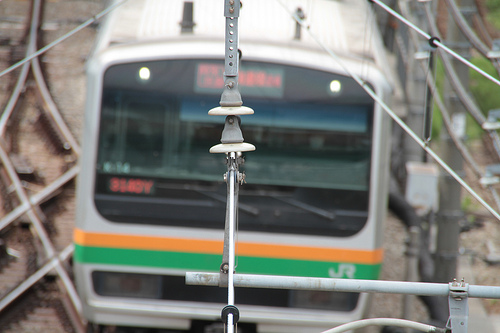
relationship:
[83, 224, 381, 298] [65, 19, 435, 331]
stripes on a train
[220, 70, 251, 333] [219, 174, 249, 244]
silver pole apparatus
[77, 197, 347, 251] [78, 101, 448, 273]
front windshield of a bus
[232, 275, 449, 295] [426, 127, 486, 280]
metal railing connected to wires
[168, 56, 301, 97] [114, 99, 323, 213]
train name and location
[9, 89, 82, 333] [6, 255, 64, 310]
railroad tracks crossing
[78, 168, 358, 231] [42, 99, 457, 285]
windshield wipers on train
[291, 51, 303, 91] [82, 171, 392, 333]
exhaust on top of train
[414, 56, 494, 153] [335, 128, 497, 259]
grass behind railroad station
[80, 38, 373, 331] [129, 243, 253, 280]
front of a train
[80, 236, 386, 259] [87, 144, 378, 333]
orange and green lines on front of train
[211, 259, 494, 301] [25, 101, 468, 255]
metal pole in picture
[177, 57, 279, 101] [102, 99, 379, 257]
electronic sign on train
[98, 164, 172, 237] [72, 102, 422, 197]
electronic sign on train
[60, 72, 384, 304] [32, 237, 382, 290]
front window on train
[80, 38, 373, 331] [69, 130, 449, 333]
front right light on train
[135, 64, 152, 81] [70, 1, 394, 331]
light lit on train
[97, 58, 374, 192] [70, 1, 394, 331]
front window built into train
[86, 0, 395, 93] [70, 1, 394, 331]
top covering train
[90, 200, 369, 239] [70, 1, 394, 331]
edge lining train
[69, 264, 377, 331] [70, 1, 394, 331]
bottom belonging to train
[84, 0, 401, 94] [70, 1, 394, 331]
roof covering train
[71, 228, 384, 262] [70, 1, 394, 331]
stripe painted on train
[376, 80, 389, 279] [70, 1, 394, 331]
edge lining train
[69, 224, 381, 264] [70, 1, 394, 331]
stripes painted on train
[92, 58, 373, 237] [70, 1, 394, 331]
windshield built into train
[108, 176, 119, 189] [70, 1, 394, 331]
number lit up inside train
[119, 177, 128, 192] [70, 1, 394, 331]
number lit up inside train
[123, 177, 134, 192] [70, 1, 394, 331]
number lit up inside train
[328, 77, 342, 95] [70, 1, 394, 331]
light lit on train